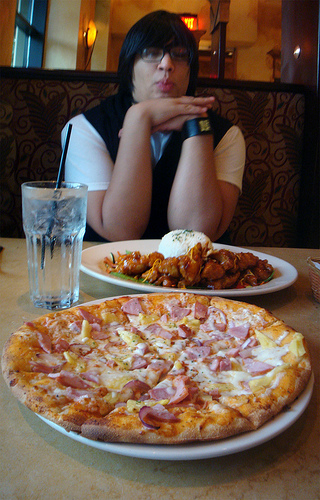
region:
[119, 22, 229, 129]
the head of a person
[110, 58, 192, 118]
the head of a person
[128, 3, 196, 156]
the head of a person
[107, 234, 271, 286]
this is food on plate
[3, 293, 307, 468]
this is a plate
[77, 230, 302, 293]
this is a plate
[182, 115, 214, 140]
this is a bracelet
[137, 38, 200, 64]
this is a pair of glasses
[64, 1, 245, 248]
this is a person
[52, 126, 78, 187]
this is a straw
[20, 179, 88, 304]
this is a glass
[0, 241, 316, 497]
this is a table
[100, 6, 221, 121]
head of a person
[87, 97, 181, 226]
arm of a person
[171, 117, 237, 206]
arm of a person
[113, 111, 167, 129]
wrist of a person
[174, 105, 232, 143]
wrist of a person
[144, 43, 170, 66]
eye of a person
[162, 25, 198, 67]
eye of a person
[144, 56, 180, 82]
nose of a person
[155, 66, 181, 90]
mouth of a person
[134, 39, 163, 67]
an eye of a person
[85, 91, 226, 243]
the person is wearing a vest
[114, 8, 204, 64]
the person is wearing a hat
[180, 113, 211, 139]
the person is wearing a wrist band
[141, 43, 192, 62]
the person is wearing glasses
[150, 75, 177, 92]
the person is puckering up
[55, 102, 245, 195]
the person is wearing a white shirt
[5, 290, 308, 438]
the pizza is on a tray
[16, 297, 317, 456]
the tray is white in color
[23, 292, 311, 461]
the tray is made of ceramic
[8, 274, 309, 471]
a pizza on a plate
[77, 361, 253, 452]
a slice of pizza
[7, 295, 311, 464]
a hawaiian pizza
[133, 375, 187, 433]
a piece of ham on pizza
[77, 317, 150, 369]
slices of pineapple on pizza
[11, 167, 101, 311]
a glass of water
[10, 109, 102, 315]
a glass with a straw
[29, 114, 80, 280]
a black straw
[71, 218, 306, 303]
a plate of food on a white dish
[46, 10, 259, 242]
a person posing for a picture